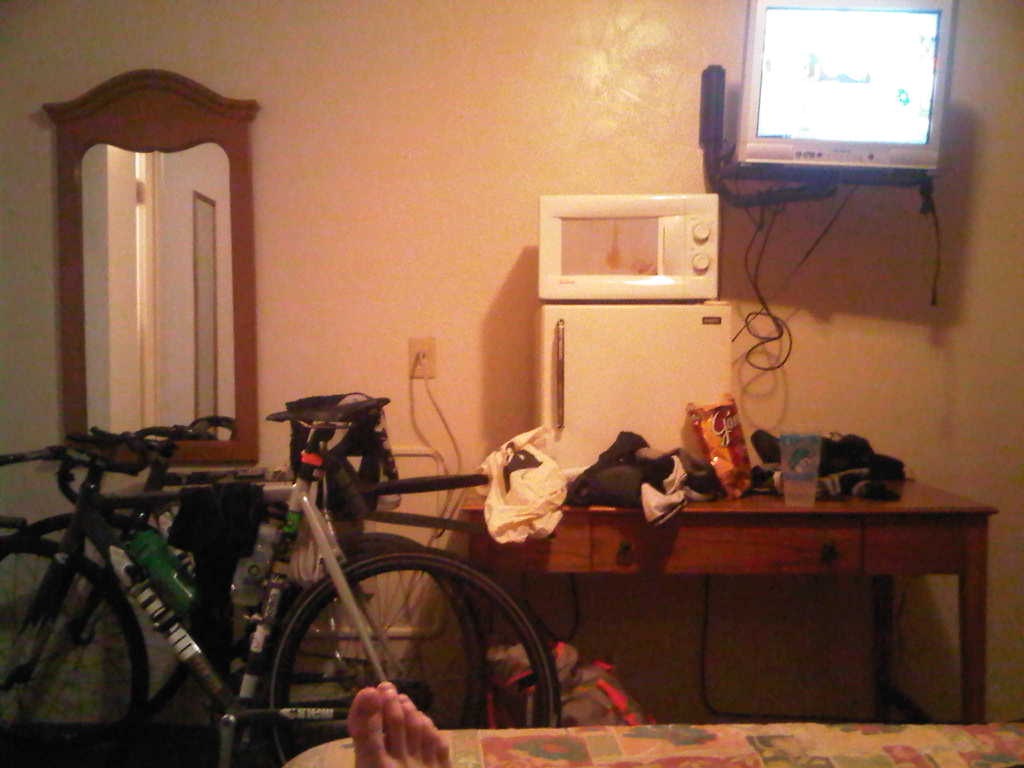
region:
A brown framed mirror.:
[39, 68, 261, 467]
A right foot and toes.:
[348, 678, 454, 765]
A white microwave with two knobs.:
[538, 191, 717, 300]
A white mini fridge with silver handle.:
[534, 298, 734, 476]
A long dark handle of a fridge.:
[553, 318, 567, 430]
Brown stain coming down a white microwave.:
[604, 222, 623, 267]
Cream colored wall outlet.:
[408, 337, 440, 382]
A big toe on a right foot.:
[345, 687, 384, 757]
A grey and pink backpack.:
[485, 634, 645, 724]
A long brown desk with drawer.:
[459, 472, 997, 726]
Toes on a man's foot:
[339, 682, 475, 766]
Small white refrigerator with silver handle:
[510, 294, 748, 491]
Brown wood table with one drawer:
[441, 470, 999, 720]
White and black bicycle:
[11, 427, 580, 754]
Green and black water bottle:
[118, 511, 207, 619]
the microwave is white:
[537, 186, 716, 300]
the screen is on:
[742, 4, 957, 160]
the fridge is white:
[537, 307, 727, 475]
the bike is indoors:
[3, 408, 558, 766]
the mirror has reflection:
[85, 146, 231, 445]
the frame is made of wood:
[41, 78, 256, 470]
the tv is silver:
[721, 0, 956, 179]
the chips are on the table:
[698, 401, 755, 501]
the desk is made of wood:
[454, 476, 995, 729]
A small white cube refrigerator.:
[538, 298, 729, 477]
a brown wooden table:
[448, 478, 1003, 738]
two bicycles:
[8, 412, 558, 763]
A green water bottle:
[121, 522, 204, 617]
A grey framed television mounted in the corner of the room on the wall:
[716, 8, 966, 177]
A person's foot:
[318, 676, 464, 766]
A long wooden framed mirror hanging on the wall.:
[39, 61, 278, 464]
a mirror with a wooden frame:
[37, 63, 262, 469]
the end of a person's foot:
[344, 674, 449, 761]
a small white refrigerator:
[530, 303, 737, 462]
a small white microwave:
[533, 189, 723, 303]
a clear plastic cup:
[778, 427, 824, 505]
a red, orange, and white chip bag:
[686, 391, 754, 496]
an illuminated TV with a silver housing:
[730, 2, 956, 183]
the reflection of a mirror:
[189, 190, 221, 422]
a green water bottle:
[119, 515, 193, 614]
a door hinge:
[128, 176, 149, 214]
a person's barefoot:
[349, 680, 455, 766]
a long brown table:
[462, 478, 997, 729]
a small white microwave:
[538, 193, 722, 296]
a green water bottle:
[122, 522, 199, 606]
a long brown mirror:
[40, 67, 272, 463]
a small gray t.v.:
[724, 0, 950, 186]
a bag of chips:
[675, 394, 762, 499]